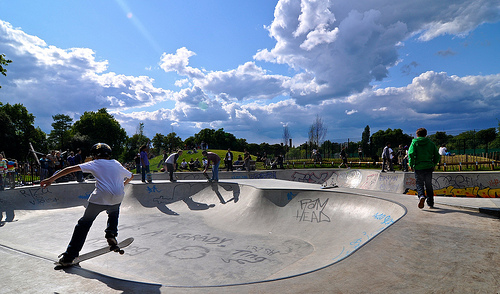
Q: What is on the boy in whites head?
A: A cap.